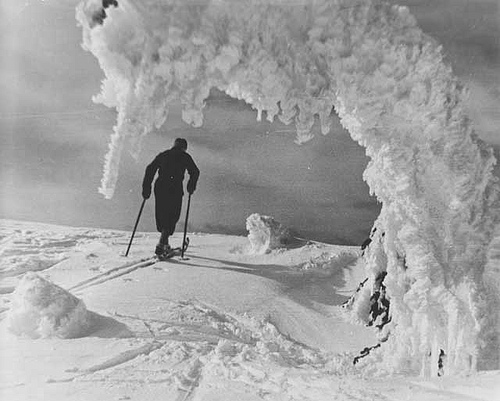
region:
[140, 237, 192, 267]
Two skis on a man's feet.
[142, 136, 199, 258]
A man skiing in all black.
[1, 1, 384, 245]
Dark grey sky.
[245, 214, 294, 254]
Lump of snow to the guy's right.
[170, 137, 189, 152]
Back of a man's head.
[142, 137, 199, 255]
A man with dark hair skiing.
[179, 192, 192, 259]
Black ski pole on the right of a man.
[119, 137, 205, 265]
man cross country skiing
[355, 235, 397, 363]
rock visible through snow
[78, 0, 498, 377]
curved overhanging sculpture made of ice and snow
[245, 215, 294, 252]
snow covered rock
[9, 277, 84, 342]
snow covered rock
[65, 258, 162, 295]
tracks left by skier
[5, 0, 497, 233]
stormy looking background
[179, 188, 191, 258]
ski pole held in skiers right hand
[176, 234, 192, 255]
curved front of ski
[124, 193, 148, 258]
ski pole held in skiers left hand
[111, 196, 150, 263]
black metal ski pole on left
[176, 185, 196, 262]
black metal ski pole on right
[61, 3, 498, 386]
tree bent into curve with icicles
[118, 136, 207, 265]
black sillouette of man on skis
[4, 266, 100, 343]
large rock cover in ice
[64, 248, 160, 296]
tracks made by skis in snow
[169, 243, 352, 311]
shadow of man on ground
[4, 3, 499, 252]
dark gray cloud filled sky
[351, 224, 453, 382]
black bits of bark in snow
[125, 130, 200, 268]
a skiier prepares to take off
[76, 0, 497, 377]
a large hook of ice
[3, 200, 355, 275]
a steep snowy hill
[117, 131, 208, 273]
a man in a snow suit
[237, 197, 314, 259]
a rock covered in ice sticks up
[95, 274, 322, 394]
ski marks left in the snow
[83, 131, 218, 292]
a skiier leaves tracks behing him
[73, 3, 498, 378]
an odd rock formation covered in ice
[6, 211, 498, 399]
a snow covered slope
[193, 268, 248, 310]
the snow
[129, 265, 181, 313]
the snow is white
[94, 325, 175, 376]
the white snow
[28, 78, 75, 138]
a cloudy sky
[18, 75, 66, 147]
the sky is cloudy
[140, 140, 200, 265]
a person skiing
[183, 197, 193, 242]
a ski pole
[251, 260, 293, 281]
a shadow on the snow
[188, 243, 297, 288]
the persons shadow on the snow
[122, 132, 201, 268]
man in black skiing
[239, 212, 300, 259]
snow covered rock on ground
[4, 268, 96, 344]
snow covered rock behind man